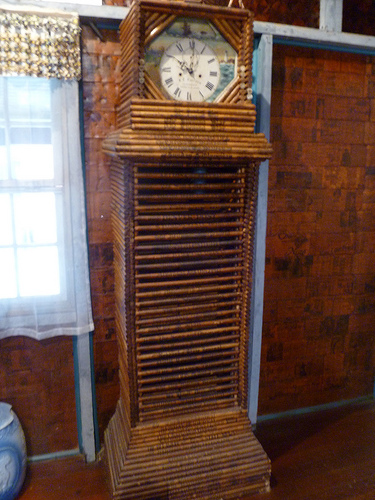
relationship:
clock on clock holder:
[147, 28, 234, 104] [102, 1, 274, 500]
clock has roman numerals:
[144, 15, 237, 102] [174, 42, 184, 53]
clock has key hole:
[144, 15, 237, 102] [177, 71, 183, 76]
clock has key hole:
[144, 15, 237, 102] [197, 71, 204, 81]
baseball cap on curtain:
[0, 8, 82, 81] [1, 5, 96, 339]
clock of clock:
[144, 15, 237, 102] [144, 15, 237, 102]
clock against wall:
[144, 15, 237, 102] [258, 0, 372, 427]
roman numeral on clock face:
[185, 88, 194, 101] [154, 34, 225, 104]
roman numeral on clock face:
[206, 70, 218, 79] [154, 34, 225, 104]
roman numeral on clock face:
[188, 39, 196, 52] [154, 34, 225, 104]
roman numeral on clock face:
[160, 65, 171, 74] [154, 34, 225, 104]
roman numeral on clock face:
[173, 83, 182, 99] [154, 34, 225, 104]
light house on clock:
[217, 49, 237, 67] [131, 12, 253, 330]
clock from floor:
[144, 15, 237, 102] [16, 407, 373, 499]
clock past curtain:
[144, 15, 237, 102] [0, 1, 95, 340]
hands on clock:
[167, 48, 202, 76] [131, 0, 249, 144]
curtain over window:
[1, 5, 96, 339] [1, 75, 68, 305]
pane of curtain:
[0, 72, 62, 298] [0, 1, 95, 340]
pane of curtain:
[0, 79, 14, 120] [0, 1, 95, 340]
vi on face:
[185, 90, 193, 103] [135, 44, 228, 117]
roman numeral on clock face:
[210, 71, 218, 76] [155, 35, 224, 99]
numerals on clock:
[162, 40, 217, 100] [137, 22, 240, 102]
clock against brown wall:
[144, 15, 237, 102] [0, 1, 375, 462]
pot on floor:
[0, 401, 26, 499] [284, 436, 345, 490]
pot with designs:
[0, 400, 29, 498] [1, 439, 31, 496]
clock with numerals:
[144, 15, 237, 102] [161, 37, 225, 98]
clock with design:
[144, 15, 237, 102] [142, 40, 167, 69]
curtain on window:
[0, 1, 95, 340] [1, 75, 68, 305]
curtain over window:
[1, 5, 96, 339] [0, 74, 64, 317]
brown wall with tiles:
[0, 1, 375, 462] [293, 87, 351, 166]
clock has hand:
[144, 15, 237, 102] [169, 56, 188, 75]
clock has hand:
[144, 15, 237, 102] [191, 45, 197, 77]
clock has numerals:
[144, 15, 237, 102] [186, 36, 194, 48]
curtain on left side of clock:
[0, 1, 95, 340] [135, 4, 259, 154]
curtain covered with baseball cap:
[0, 1, 95, 340] [0, 8, 82, 81]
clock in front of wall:
[121, 7, 272, 128] [11, 6, 349, 430]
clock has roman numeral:
[144, 15, 237, 102] [187, 91, 192, 100]